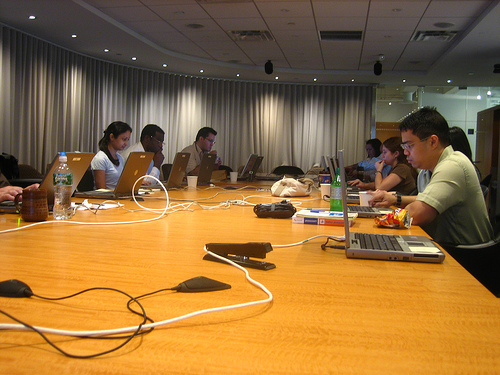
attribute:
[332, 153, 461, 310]
laptop — open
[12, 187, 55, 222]
cup — Brown 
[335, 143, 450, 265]
laptop — Gray 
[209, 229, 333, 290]
stapler — black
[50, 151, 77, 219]
waterbottle — clear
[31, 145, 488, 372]
table — wood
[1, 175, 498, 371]
table — Wood , yellow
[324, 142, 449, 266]
laptop — Silver 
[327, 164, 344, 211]
soda bottle — Green 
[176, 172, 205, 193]
coffee — Brown 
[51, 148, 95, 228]
bottle — Blue 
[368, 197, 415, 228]
bag — Open 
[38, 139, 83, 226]
bottle — plastic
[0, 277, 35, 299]
mouse — black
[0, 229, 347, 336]
ethernet cable — white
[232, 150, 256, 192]
lap top — Gray 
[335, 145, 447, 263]
lap top — Gray 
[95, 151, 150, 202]
lap top — Gray 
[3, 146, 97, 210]
lap top — Gray 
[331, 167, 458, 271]
laptop — gray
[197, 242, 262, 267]
stapler — Brown 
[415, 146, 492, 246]
shirt — green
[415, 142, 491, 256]
shirt — green